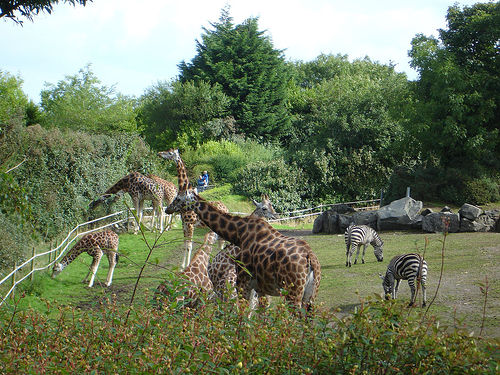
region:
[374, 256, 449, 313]
a zebrea eating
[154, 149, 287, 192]
a man riding a giraffe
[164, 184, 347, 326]
a giraffe in the front of the scene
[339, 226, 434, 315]
two zebras eating grass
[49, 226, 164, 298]
a giraffe eating grass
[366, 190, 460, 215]
rocks in the back ground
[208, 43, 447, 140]
some trees in the back ground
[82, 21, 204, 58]
a partly cloudy sky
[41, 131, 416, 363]
five giraffes in the scene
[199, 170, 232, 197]
a man wearing a blue shirt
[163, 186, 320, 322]
brown and tan giraffe in tall grass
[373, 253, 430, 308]
black and white zebra grazing in grass field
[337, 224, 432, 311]
two black and white zebras grazing on grass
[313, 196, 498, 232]
pile of large grey rocks and boulders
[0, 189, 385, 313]
long wooden fence enclosure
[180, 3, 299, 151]
tall green tree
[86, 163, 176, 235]
tall green giraffe grazing from shrubs and foliage beyond fence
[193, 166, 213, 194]
person in blue standing on other side of giraffe fence enclosure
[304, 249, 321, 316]
brown and tan giraffe tail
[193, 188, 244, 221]
brown giraffe mane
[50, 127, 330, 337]
a few giraffes in enclosure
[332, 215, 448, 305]
a pair of zebras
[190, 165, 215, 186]
a man in blue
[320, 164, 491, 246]
a pile of boulders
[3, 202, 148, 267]
a short wood fence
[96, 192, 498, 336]
a field with patchy grass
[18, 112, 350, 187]
a variety of tall plants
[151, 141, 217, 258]
a giraffe with outstretched neck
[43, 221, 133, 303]
a young giraffe grazing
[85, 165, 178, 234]
a pair of brown and white animals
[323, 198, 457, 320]
The zebras are grazing.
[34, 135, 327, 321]
The giraffe are eating.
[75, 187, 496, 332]
The grass is green.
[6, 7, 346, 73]
The sky is blue.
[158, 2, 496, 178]
The trees are green.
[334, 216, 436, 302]
The zebras are black and white.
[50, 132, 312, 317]
The giraffe are brown and tan.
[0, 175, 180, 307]
The fence is wooden.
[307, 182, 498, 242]
The rocks are grey.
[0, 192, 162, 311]
The fence is brown.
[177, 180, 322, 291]
giraffes with brown and block spots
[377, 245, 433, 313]
zebra with black stripes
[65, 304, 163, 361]
green bush with branches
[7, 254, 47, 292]
wood fence on grassy area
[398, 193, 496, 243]
large rocks near green grass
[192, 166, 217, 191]
man with blue shirt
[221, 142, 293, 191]
green and large bushes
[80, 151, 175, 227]
giraffes eating leaves off a tree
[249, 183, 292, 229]
white and brown giraffe face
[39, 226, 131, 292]
baby giraffe eating grass